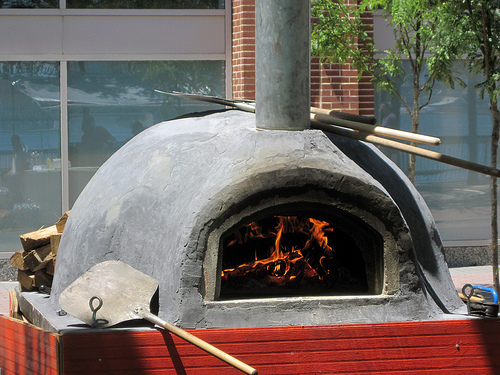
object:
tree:
[307, 0, 500, 187]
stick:
[308, 110, 441, 146]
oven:
[48, 0, 474, 320]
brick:
[333, 75, 349, 83]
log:
[18, 225, 57, 248]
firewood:
[20, 225, 58, 251]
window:
[67, 62, 230, 211]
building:
[0, 0, 495, 248]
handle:
[89, 296, 102, 327]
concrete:
[443, 249, 497, 296]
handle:
[469, 284, 497, 305]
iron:
[465, 285, 498, 321]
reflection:
[71, 108, 117, 166]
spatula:
[55, 258, 254, 375]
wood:
[231, 235, 294, 265]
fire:
[217, 220, 335, 283]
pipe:
[256, 0, 313, 130]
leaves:
[329, 16, 341, 27]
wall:
[229, 0, 374, 115]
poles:
[154, 91, 500, 179]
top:
[158, 103, 396, 185]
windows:
[67, 65, 230, 251]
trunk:
[407, 26, 424, 182]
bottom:
[0, 315, 499, 375]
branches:
[410, 25, 422, 182]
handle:
[137, 313, 260, 375]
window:
[2, 63, 61, 252]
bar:
[56, 59, 68, 220]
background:
[0, 0, 500, 375]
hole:
[214, 202, 382, 303]